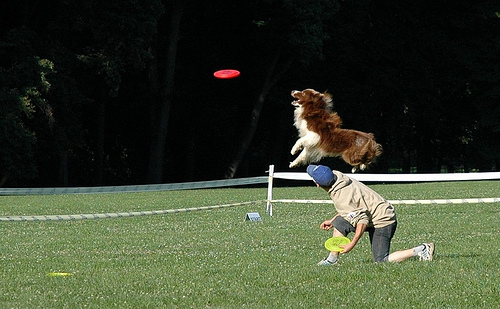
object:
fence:
[0, 171, 499, 221]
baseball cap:
[304, 165, 335, 188]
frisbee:
[321, 236, 352, 253]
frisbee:
[212, 64, 241, 80]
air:
[0, 0, 499, 189]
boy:
[305, 165, 436, 268]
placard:
[245, 212, 260, 220]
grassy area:
[0, 171, 497, 307]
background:
[0, 0, 498, 190]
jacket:
[326, 169, 398, 229]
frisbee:
[49, 272, 70, 277]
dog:
[289, 88, 383, 174]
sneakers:
[416, 241, 436, 263]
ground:
[3, 197, 127, 256]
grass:
[0, 180, 500, 308]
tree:
[0, 0, 500, 184]